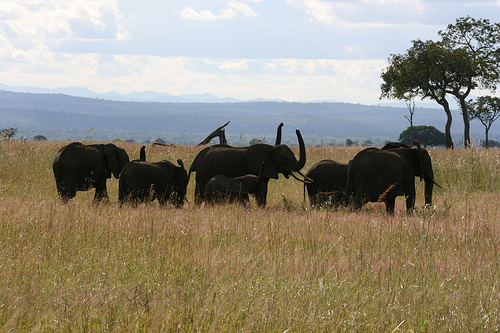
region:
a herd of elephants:
[35, 123, 447, 228]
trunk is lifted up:
[284, 126, 315, 183]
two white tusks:
[287, 168, 312, 188]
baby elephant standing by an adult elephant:
[190, 131, 315, 205]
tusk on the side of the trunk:
[429, 176, 444, 193]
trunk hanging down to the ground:
[422, 162, 439, 210]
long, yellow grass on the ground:
[3, 143, 493, 332]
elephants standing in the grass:
[39, 111, 461, 226]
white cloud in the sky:
[174, 2, 252, 26]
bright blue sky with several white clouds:
[2, 4, 490, 110]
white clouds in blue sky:
[0, 1, 499, 102]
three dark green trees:
[377, 9, 498, 158]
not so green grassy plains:
[2, 139, 496, 331]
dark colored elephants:
[40, 114, 447, 221]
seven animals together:
[46, 114, 443, 221]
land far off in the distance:
[4, 88, 499, 148]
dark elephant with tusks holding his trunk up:
[189, 125, 311, 212]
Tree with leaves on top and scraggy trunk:
[375, 31, 477, 153]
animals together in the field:
[49, 117, 444, 213]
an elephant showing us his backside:
[342, 133, 442, 214]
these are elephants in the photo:
[45, 134, 440, 213]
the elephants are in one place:
[47, 124, 447, 228]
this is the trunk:
[291, 123, 308, 163]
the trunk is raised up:
[289, 127, 310, 160]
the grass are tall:
[232, 212, 437, 323]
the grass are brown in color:
[121, 217, 416, 332]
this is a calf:
[197, 168, 269, 206]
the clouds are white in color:
[254, 1, 348, 44]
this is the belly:
[373, 151, 404, 176]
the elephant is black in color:
[65, 145, 102, 175]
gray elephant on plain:
[48, 133, 141, 209]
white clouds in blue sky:
[46, 20, 112, 55]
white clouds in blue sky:
[145, 17, 245, 77]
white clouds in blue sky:
[250, 20, 296, 65]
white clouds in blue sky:
[291, 60, 371, 105]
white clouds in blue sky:
[330, 5, 402, 60]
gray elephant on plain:
[117, 151, 177, 202]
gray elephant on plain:
[190, 123, 310, 216]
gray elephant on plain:
[325, 155, 395, 225]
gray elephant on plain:
[363, 129, 450, 216]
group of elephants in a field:
[47, 124, 447, 217]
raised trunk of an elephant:
[292, 124, 312, 168]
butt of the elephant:
[47, 144, 88, 184]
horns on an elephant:
[284, 167, 319, 187]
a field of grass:
[27, 201, 477, 331]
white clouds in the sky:
[27, 9, 432, 57]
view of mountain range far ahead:
[7, 76, 298, 111]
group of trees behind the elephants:
[389, 8, 491, 149]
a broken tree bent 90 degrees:
[195, 118, 235, 145]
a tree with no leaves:
[400, 99, 420, 124]